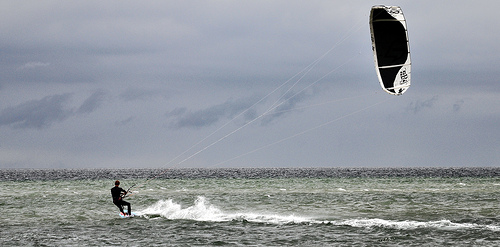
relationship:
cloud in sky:
[2, 50, 115, 136] [2, 2, 499, 174]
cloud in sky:
[144, 71, 331, 134] [2, 2, 499, 174]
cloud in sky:
[387, 75, 492, 126] [2, 2, 499, 174]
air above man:
[0, 0, 499, 169] [85, 145, 166, 229]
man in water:
[110, 180, 132, 216] [253, 182, 453, 229]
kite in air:
[368, 5, 412, 97] [324, 8, 489, 162]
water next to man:
[177, 187, 234, 231] [102, 173, 143, 220]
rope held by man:
[157, 15, 398, 172] [112, 179, 132, 217]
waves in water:
[115, 192, 498, 232] [1, 167, 498, 245]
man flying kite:
[110, 180, 133, 215] [369, 3, 411, 95]